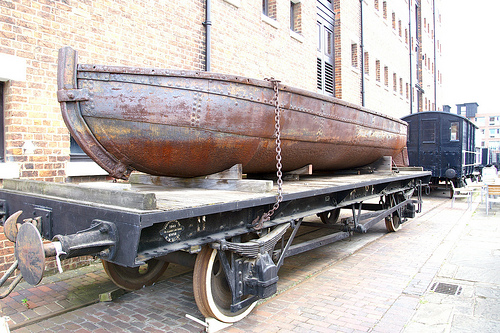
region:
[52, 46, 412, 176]
Meal oar boat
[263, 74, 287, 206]
Chain strapping the boat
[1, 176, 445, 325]
Carriage wagon on a rail track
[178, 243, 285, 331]
Wheel of a carriage wagon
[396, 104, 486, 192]
Black engine of a train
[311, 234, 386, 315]
Red brick pavement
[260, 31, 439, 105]
Large red brick building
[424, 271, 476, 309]
Meshed sewer cover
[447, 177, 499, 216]
Table and chairs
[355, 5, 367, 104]
Black colored storm drain pipe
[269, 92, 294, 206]
a heavy chain on the boat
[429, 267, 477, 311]
a vent in the sidewalk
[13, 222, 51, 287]
a metal disk attachment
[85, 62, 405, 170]
an old rusty boat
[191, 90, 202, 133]
metal bolts on the boat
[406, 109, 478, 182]
an old black train car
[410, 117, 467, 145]
windows in the train car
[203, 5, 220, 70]
a black drain pipe on the wall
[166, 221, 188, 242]
a black and white sticker in the platform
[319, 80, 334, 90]
shutters on window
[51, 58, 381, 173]
Boat is brown color.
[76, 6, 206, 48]
wall is made of brick.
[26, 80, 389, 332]
Train is on the track.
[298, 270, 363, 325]
Floor is brown color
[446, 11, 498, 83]
Sky is white color.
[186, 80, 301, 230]
Boat is tied to the cart.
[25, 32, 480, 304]
Day time picture.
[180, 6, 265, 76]
Pipe are black color.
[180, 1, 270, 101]
Pipe are attached to the wall.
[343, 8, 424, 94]
Windows are attached to the wall.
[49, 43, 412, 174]
a large brown boat.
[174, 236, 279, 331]
a wheel on a trailer.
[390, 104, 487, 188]
a train car near a building.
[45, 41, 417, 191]
a large haunted boat.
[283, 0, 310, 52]
a window on a building.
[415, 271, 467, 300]
a drain on the ground.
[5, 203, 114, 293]
a hitch on a trailer.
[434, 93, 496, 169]
tall multi story building.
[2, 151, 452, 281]
a long iron flatbed.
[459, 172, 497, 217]
a pile of clutter.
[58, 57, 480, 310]
Train is in track.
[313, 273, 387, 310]
ground is brown color.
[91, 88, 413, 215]
Boat is tied to the train cart.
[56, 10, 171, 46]
wall is red color.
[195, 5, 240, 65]
Pipe lines are attached to the wall.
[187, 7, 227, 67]
Pipes are black color.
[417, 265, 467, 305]
Drain is attached to the floor.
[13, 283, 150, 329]
Shadow falls on ground.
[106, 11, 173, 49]
Wall is made of brick.